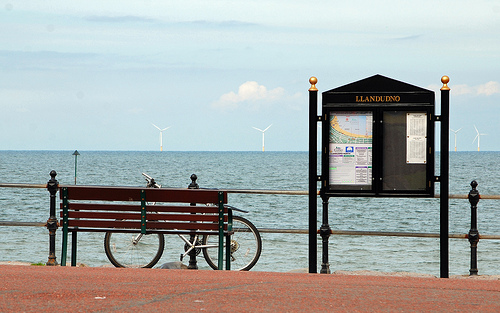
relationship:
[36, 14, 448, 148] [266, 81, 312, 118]
sky has cloud